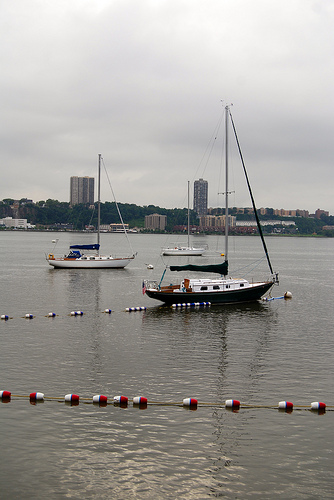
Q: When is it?
A: Day time.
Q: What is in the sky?
A: Clouds.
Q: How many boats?
A: 3.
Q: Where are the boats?
A: On the water.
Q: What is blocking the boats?
A: Rope.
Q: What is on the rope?
A: Floats.